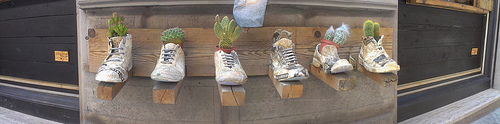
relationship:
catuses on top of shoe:
[161, 26, 184, 50] [150, 42, 185, 83]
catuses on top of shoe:
[215, 15, 244, 47] [90, 34, 133, 83]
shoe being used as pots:
[265, 44, 308, 82] [104, 14, 138, 84]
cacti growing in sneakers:
[85, 11, 145, 101] [96, 24, 405, 95]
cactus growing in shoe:
[105, 12, 128, 34] [90, 34, 133, 83]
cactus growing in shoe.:
[309, 16, 354, 47] [306, 41, 358, 75]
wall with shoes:
[87, 23, 392, 93] [357, 24, 402, 76]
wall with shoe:
[87, 23, 392, 93] [265, 44, 308, 82]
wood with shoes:
[95, 68, 397, 107] [104, 21, 413, 102]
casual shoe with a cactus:
[312, 34, 354, 79] [318, 17, 348, 49]